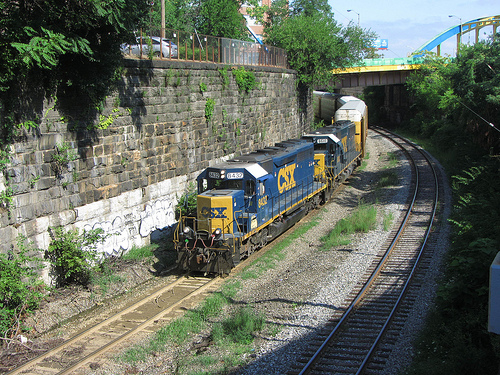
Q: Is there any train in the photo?
A: Yes, there is a train.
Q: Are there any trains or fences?
A: Yes, there is a train.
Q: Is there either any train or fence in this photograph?
A: Yes, there is a train.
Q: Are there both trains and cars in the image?
A: Yes, there are both a train and cars.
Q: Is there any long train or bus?
A: Yes, there is a long train.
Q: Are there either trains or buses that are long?
A: Yes, the train is long.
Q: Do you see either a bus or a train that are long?
A: Yes, the train is long.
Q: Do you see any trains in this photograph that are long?
A: Yes, there is a long train.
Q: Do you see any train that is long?
A: Yes, there is a train that is long.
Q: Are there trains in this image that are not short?
A: Yes, there is a long train.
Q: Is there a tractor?
A: No, there are no tractors.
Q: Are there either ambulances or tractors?
A: No, there are no tractors or ambulances.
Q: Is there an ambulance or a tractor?
A: No, there are no tractors or ambulances.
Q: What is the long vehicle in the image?
A: The vehicle is a train.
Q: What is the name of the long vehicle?
A: The vehicle is a train.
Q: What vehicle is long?
A: The vehicle is a train.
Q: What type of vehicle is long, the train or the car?
A: The train is long.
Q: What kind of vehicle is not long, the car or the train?
A: The car is not long.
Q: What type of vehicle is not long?
A: The vehicle is a car.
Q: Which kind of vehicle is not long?
A: The vehicle is a car.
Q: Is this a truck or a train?
A: This is a train.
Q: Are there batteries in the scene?
A: No, there are no batteries.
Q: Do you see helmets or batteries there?
A: No, there are no batteries or helmets.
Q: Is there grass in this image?
A: Yes, there is grass.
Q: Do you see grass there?
A: Yes, there is grass.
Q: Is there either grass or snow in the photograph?
A: Yes, there is grass.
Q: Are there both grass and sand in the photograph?
A: No, there is grass but no sand.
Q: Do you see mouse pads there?
A: No, there are no mouse pads.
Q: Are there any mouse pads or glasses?
A: No, there are no mouse pads or glasses.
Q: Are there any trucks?
A: No, there are no trucks.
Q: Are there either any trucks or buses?
A: No, there are no trucks or buses.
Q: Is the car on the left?
A: Yes, the car is on the left of the image.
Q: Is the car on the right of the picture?
A: No, the car is on the left of the image.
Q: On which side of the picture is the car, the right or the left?
A: The car is on the left of the image.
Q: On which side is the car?
A: The car is on the left of the image.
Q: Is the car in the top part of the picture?
A: Yes, the car is in the top of the image.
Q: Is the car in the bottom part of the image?
A: No, the car is in the top of the image.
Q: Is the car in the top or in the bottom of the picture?
A: The car is in the top of the image.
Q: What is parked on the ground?
A: The car is parked on the ground.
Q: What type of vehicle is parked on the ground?
A: The vehicle is a car.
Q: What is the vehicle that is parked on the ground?
A: The vehicle is a car.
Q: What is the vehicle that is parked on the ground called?
A: The vehicle is a car.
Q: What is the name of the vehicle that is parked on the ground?
A: The vehicle is a car.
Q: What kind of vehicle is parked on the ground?
A: The vehicle is a car.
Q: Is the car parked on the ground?
A: Yes, the car is parked on the ground.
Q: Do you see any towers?
A: No, there are no towers.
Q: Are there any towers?
A: No, there are no towers.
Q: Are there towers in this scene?
A: No, there are no towers.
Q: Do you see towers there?
A: No, there are no towers.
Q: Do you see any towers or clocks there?
A: No, there are no towers or clocks.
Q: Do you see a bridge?
A: Yes, there is a bridge.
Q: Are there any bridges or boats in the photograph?
A: Yes, there is a bridge.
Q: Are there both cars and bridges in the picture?
A: Yes, there are both a bridge and a car.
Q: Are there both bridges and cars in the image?
A: Yes, there are both a bridge and a car.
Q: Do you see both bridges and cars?
A: Yes, there are both a bridge and a car.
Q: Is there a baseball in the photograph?
A: No, there are no baseballs.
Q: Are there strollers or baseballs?
A: No, there are no baseballs or strollers.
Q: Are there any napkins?
A: No, there are no napkins.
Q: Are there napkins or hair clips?
A: No, there are no napkins or hair clips.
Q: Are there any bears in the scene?
A: No, there are no bears.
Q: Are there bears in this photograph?
A: No, there are no bears.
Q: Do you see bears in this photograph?
A: No, there are no bears.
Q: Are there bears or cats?
A: No, there are no bears or cats.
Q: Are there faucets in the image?
A: No, there are no faucets.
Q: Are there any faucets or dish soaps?
A: No, there are no faucets or dish soaps.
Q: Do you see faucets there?
A: No, there are no faucets.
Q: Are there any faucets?
A: No, there are no faucets.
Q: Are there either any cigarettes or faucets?
A: No, there are no faucets or cigarettes.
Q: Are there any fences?
A: Yes, there is a fence.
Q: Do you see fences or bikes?
A: Yes, there is a fence.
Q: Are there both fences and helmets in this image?
A: No, there is a fence but no helmets.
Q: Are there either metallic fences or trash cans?
A: Yes, there is a metal fence.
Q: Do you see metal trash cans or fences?
A: Yes, there is a metal fence.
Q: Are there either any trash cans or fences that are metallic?
A: Yes, the fence is metallic.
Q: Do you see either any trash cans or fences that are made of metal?
A: Yes, the fence is made of metal.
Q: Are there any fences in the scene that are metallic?
A: Yes, there is a metal fence.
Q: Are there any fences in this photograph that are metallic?
A: Yes, there is a fence that is metallic.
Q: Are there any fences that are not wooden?
A: Yes, there is a metallic fence.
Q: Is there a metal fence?
A: Yes, there is a fence that is made of metal.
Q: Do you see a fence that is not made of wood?
A: Yes, there is a fence that is made of metal.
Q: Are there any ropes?
A: No, there are no ropes.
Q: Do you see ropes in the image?
A: No, there are no ropes.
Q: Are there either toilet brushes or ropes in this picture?
A: No, there are no ropes or toilet brushes.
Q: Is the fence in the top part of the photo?
A: Yes, the fence is in the top of the image.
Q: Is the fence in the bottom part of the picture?
A: No, the fence is in the top of the image.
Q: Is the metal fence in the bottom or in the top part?
A: The fence is in the top of the image.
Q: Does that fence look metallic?
A: Yes, the fence is metallic.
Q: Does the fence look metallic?
A: Yes, the fence is metallic.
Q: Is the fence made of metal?
A: Yes, the fence is made of metal.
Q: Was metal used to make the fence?
A: Yes, the fence is made of metal.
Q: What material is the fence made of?
A: The fence is made of metal.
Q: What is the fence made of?
A: The fence is made of metal.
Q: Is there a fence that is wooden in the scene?
A: No, there is a fence but it is metallic.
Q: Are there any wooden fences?
A: No, there is a fence but it is metallic.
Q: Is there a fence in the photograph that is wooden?
A: No, there is a fence but it is metallic.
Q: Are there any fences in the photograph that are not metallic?
A: No, there is a fence but it is metallic.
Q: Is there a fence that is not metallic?
A: No, there is a fence but it is metallic.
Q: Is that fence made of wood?
A: No, the fence is made of metal.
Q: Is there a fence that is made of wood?
A: No, there is a fence but it is made of metal.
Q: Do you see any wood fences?
A: No, there is a fence but it is made of metal.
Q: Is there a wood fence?
A: No, there is a fence but it is made of metal.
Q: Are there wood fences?
A: No, there is a fence but it is made of metal.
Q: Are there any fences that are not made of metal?
A: No, there is a fence but it is made of metal.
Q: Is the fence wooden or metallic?
A: The fence is metallic.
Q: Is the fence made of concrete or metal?
A: The fence is made of metal.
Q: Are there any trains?
A: Yes, there is a train.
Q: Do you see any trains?
A: Yes, there is a train.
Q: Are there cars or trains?
A: Yes, there is a train.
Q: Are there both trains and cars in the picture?
A: Yes, there are both a train and a car.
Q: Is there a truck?
A: No, there are no trucks.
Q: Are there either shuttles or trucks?
A: No, there are no trucks or shuttles.